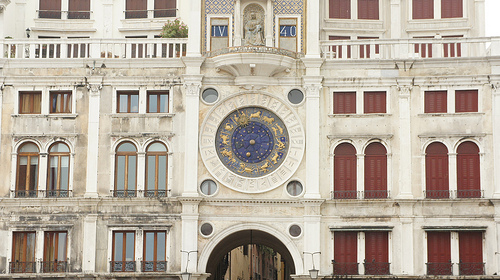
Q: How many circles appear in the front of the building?
A: Seven.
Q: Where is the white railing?
A: Along the outside edge of the third story.